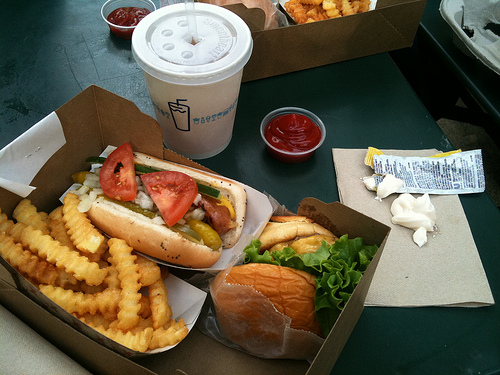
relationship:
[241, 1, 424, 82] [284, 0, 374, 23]
box with food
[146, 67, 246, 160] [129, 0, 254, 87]
cup with cover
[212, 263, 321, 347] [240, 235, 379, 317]
bun with lettuce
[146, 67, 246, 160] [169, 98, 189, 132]
cup with drawing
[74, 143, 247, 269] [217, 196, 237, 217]
dog with mustard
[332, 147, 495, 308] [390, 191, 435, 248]
napkin with mayo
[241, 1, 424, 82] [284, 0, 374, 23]
box of fries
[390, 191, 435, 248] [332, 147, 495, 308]
mayo on napkin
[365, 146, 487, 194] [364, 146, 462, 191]
mayonaisse and mustard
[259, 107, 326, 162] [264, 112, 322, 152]
cup of ketchup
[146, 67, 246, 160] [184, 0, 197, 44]
cup with straw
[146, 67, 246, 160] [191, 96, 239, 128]
cup with writing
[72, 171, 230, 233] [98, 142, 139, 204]
dog with tomato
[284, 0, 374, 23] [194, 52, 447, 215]
food on table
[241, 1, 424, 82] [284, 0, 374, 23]
box full of food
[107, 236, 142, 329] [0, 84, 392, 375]
fry inside box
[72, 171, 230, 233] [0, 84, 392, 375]
dog inside box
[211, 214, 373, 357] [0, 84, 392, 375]
hamburger inside box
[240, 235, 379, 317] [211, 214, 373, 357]
lettuce on hamburger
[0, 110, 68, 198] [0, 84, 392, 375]
receipt on side of box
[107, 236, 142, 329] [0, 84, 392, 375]
fry in box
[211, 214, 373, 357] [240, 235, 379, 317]
hamburger with lettuce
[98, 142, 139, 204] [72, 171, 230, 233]
tomato on dog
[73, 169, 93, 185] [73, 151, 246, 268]
pickle at end of bun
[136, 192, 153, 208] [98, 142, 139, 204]
onion next to tomato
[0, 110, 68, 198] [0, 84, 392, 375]
receipt stapled to side of box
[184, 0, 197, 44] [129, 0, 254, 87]
straw through cover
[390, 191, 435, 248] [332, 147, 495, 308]
mayo squeezed onto napkin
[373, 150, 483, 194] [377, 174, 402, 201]
mayonaisse with sauce